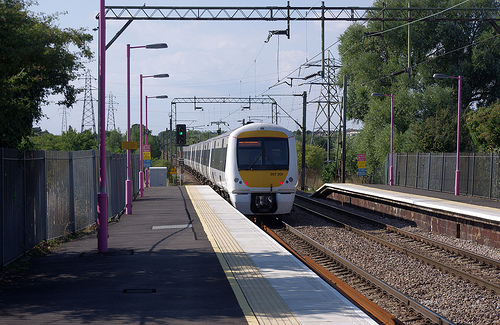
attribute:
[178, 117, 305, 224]
train — long, electric, white, yellow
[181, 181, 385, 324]
platform — white, tan, empty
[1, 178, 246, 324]
ground — paved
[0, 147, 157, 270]
fencing — black, metal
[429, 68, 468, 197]
pole — purple, tall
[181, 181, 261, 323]
line — the color yellow, yellow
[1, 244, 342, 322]
shadow — large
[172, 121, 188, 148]
sign — green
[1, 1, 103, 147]
tree — green, large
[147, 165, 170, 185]
structure — metalic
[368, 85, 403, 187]
light — red, off, tall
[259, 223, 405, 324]
rail — rusted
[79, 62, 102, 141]
line — tall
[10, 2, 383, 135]
sky — blue